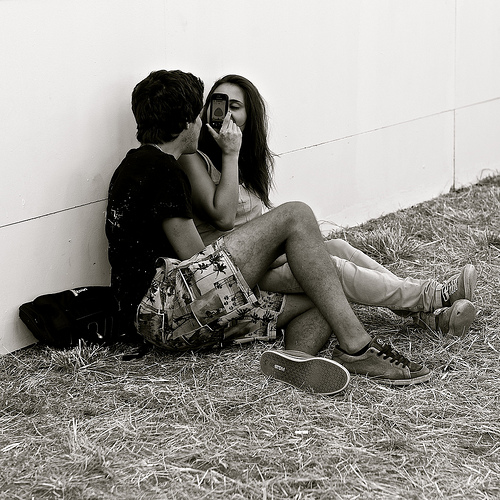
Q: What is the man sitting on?
A: Grass.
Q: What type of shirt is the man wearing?
A: A black tshirt.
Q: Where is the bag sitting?
A: On the grass.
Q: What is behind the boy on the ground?
A: Bag.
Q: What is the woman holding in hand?
A: Cellphone.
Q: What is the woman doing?
A: Taking a picture.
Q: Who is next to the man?
A: A woman.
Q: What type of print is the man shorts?
A: Tropical.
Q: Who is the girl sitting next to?
A: Boyfriend.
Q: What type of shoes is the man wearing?
A: Sneakers.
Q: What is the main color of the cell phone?
A: Gray.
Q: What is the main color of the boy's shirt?
A: Black.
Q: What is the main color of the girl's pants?
A: Gray.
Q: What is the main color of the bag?
A: Black.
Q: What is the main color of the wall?
A: White.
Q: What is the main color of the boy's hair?
A: Black.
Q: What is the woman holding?
A: A cell phone.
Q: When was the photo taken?
A: Daytime.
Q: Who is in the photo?
A: A man and a woman.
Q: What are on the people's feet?
A: Sneakers.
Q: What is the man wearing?
A: A t-shirt, shorts and sneakers.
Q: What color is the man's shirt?
A: Black.